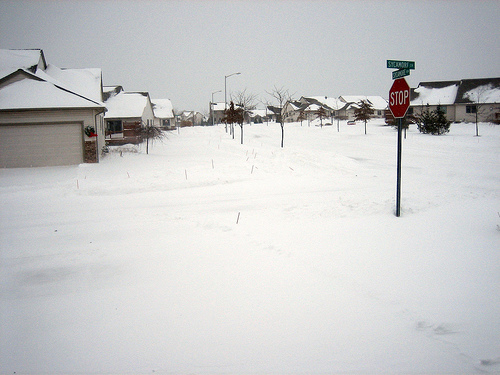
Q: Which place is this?
A: It is a yard.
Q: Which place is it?
A: It is a yard.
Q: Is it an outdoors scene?
A: Yes, it is outdoors.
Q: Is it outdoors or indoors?
A: It is outdoors.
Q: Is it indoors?
A: No, it is outdoors.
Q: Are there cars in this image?
A: No, there are no cars.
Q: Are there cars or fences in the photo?
A: No, there are no cars or fences.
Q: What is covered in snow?
A: The yard is covered in snow.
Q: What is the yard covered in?
A: The yard is covered in snow.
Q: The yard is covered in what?
A: The yard is covered in snow.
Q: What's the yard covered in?
A: The yard is covered in snow.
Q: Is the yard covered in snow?
A: Yes, the yard is covered in snow.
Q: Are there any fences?
A: No, there are no fences.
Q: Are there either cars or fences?
A: No, there are no fences or cars.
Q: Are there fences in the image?
A: No, there are no fences.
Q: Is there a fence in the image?
A: No, there are no fences.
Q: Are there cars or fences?
A: No, there are no fences or cars.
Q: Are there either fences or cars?
A: No, there are no fences or cars.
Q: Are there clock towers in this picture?
A: No, there are no clock towers.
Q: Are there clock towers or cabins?
A: No, there are no clock towers or cabins.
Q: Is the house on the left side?
A: Yes, the house is on the left of the image.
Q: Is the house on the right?
A: No, the house is on the left of the image.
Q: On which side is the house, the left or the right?
A: The house is on the left of the image.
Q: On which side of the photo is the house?
A: The house is on the left of the image.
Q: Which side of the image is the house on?
A: The house is on the left of the image.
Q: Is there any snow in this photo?
A: Yes, there is snow.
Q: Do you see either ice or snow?
A: Yes, there is snow.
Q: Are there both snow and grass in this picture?
A: No, there is snow but no grass.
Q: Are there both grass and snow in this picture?
A: No, there is snow but no grass.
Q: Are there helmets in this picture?
A: No, there are no helmets.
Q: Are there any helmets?
A: No, there are no helmets.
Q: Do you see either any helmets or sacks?
A: No, there are no helmets or sacks.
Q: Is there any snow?
A: Yes, there is snow.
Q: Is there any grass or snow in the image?
A: Yes, there is snow.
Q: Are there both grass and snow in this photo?
A: No, there is snow but no grass.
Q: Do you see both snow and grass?
A: No, there is snow but no grass.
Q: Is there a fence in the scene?
A: No, there are no fences.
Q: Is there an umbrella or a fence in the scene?
A: No, there are no fences or umbrellas.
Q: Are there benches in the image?
A: No, there are no benches.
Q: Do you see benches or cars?
A: No, there are no benches or cars.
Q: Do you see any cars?
A: No, there are no cars.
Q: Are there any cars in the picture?
A: No, there are no cars.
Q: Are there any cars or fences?
A: No, there are no cars or fences.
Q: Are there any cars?
A: No, there are no cars.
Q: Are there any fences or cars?
A: No, there are no cars or fences.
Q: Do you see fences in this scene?
A: No, there are no fences.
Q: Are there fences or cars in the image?
A: No, there are no fences or cars.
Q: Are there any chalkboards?
A: No, there are no chalkboards.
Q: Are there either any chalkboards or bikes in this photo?
A: No, there are no chalkboards or bikes.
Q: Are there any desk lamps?
A: No, there are no desk lamps.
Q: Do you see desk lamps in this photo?
A: No, there are no desk lamps.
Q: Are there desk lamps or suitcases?
A: No, there are no desk lamps or suitcases.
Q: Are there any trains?
A: No, there are no trains.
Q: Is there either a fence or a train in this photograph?
A: No, there are no trains or fences.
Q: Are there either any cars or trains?
A: No, there are no trains or cars.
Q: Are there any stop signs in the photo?
A: Yes, there is a stop sign.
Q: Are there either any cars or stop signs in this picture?
A: Yes, there is a stop sign.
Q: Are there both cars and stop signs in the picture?
A: No, there is a stop sign but no cars.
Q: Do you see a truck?
A: No, there are no trucks.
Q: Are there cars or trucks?
A: No, there are no trucks or cars.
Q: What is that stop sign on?
A: The stop sign is on the pole.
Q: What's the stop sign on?
A: The stop sign is on the pole.